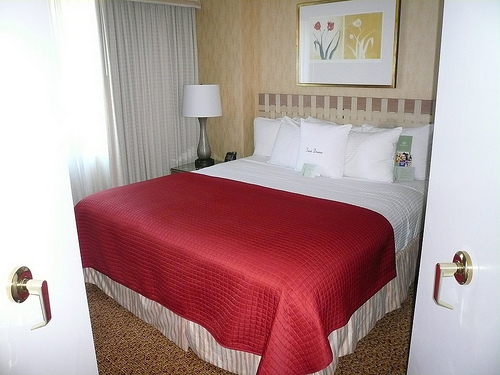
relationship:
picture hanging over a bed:
[292, 8, 404, 97] [100, 142, 385, 366]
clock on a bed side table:
[222, 151, 235, 163] [170, 156, 234, 177]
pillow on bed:
[292, 115, 352, 182] [68, 112, 435, 368]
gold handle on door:
[428, 248, 481, 318] [422, 17, 499, 278]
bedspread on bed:
[70, 169, 401, 361] [68, 112, 435, 368]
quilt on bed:
[86, 174, 433, 373] [68, 112, 435, 368]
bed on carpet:
[68, 112, 435, 368] [82, 281, 415, 374]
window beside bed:
[55, 0, 121, 202] [68, 112, 435, 368]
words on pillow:
[307, 143, 328, 160] [289, 112, 346, 179]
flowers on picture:
[303, 12, 383, 59] [289, 0, 417, 90]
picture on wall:
[297, 4, 402, 90] [235, 36, 306, 101]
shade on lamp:
[181, 82, 221, 118] [181, 83, 221, 170]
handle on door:
[12, 266, 51, 332] [0, 3, 96, 353]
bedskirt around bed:
[87, 284, 255, 374] [68, 112, 435, 368]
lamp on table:
[145, 44, 252, 175] [171, 158, 226, 174]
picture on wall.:
[294, 0, 398, 85] [218, 21, 275, 68]